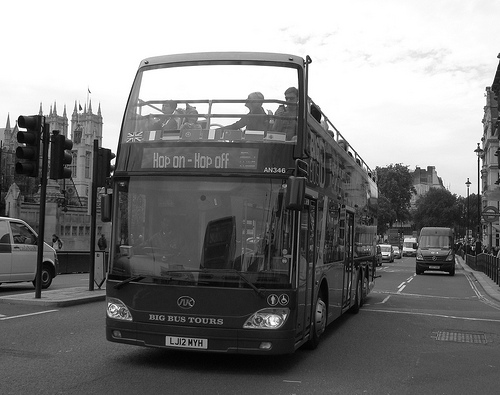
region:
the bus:
[82, 77, 465, 352]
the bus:
[52, 27, 333, 280]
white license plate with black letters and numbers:
[159, 333, 211, 351]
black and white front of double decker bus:
[93, 40, 326, 362]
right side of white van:
[3, 207, 60, 298]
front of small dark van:
[412, 218, 457, 280]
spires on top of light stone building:
[43, 78, 107, 125]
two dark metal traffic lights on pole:
[16, 105, 73, 315]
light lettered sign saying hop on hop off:
[131, 143, 246, 173]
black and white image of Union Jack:
[121, 128, 151, 143]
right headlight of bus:
[99, 292, 138, 327]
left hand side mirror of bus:
[284, 157, 309, 217]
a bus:
[70, 34, 385, 394]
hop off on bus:
[193, 151, 235, 172]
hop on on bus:
[144, 147, 186, 168]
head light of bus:
[240, 308, 290, 334]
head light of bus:
[100, 297, 132, 324]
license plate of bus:
[153, 331, 214, 355]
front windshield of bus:
[120, 165, 292, 292]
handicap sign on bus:
[280, 293, 290, 308]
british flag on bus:
[114, 127, 146, 144]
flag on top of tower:
[73, 77, 98, 115]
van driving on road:
[403, 210, 465, 281]